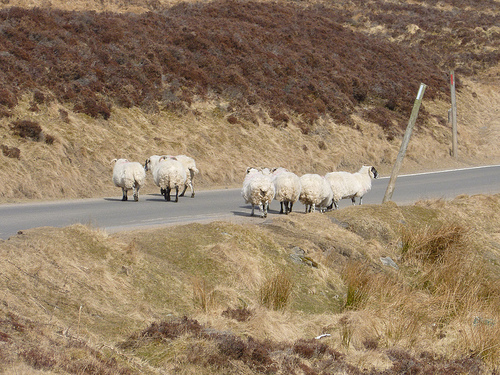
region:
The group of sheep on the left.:
[104, 142, 204, 205]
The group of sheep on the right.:
[245, 164, 379, 214]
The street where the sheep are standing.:
[8, 164, 495, 224]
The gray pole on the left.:
[448, 68, 461, 165]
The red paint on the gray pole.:
[449, 73, 453, 86]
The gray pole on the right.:
[376, 84, 428, 204]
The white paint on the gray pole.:
[417, 84, 422, 97]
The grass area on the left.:
[22, 218, 498, 373]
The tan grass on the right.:
[11, 106, 498, 170]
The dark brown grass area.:
[11, 5, 456, 141]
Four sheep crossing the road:
[238, 142, 378, 223]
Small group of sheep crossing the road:
[106, 146, 376, 218]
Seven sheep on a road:
[106, 146, 376, 221]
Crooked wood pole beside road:
[376, 76, 426, 206]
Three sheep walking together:
[96, 145, 197, 205]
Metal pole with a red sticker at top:
[440, 66, 465, 156]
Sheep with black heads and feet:
[105, 150, 380, 220]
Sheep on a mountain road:
[0, 0, 499, 240]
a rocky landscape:
[266, 221, 412, 318]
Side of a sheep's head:
[357, 160, 379, 180]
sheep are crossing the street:
[85, 130, 410, 219]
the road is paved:
[37, 175, 234, 255]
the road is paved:
[37, 185, 201, 232]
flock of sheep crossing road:
[110, 155, 374, 216]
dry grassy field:
[7, 193, 497, 373]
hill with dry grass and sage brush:
[2, 0, 499, 200]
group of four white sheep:
[242, 164, 378, 212]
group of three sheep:
[111, 150, 195, 202]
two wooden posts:
[404, 81, 459, 157]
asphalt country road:
[1, 164, 499, 232]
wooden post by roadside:
[382, 82, 428, 200]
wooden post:
[449, 69, 456, 156]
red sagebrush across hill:
[0, 0, 499, 157]